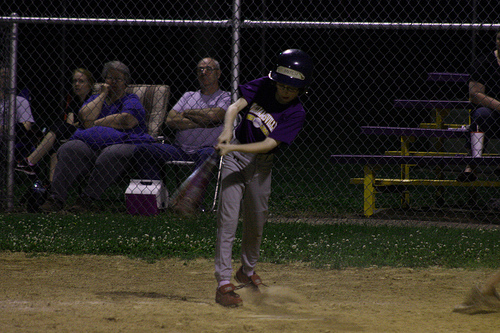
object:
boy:
[211, 49, 310, 308]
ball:
[31, 181, 41, 190]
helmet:
[269, 48, 315, 94]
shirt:
[237, 75, 307, 152]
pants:
[215, 150, 271, 282]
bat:
[199, 153, 222, 213]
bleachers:
[360, 125, 473, 136]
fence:
[0, 0, 500, 229]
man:
[465, 37, 500, 124]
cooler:
[122, 178, 170, 210]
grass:
[0, 211, 500, 268]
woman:
[39, 61, 152, 213]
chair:
[112, 85, 165, 141]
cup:
[468, 133, 481, 156]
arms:
[185, 91, 233, 124]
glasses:
[103, 79, 126, 84]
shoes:
[212, 284, 241, 306]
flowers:
[296, 231, 304, 239]